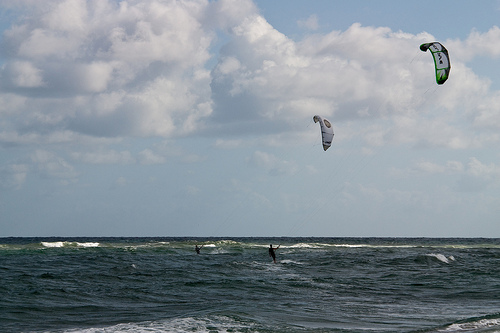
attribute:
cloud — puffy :
[10, 155, 30, 189]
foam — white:
[82, 321, 252, 331]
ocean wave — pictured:
[293, 241, 390, 258]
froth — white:
[417, 247, 463, 277]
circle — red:
[321, 109, 333, 132]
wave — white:
[211, 262, 443, 293]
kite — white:
[281, 80, 386, 168]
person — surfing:
[264, 239, 284, 264]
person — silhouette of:
[266, 242, 276, 263]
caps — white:
[42, 237, 98, 248]